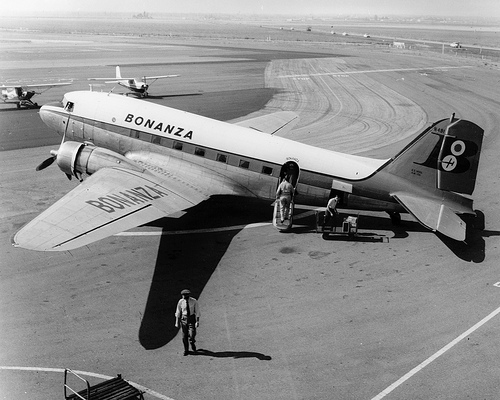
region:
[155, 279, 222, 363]
Person wearing a tie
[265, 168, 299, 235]
Person climbing up the stairs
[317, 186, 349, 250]
Person grabbing a package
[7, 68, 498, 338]
Large plane on the runway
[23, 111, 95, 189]
Large metal airplane propeller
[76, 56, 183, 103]
Small propeller based airplane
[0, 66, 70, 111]
Small propeller based airplane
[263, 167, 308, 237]
Person climbing into an airplane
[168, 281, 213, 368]
Person walking away from an airplane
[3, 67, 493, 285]
Large airplane parked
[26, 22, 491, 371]
A black and white picture.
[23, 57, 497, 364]
Picture of an older airplane.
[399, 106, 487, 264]
The tail of an airplane.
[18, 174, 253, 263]
Left wing of an airplane.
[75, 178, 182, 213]
The word BONANZA on the left wing of airplane.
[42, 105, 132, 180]
Left side engine on an airplane.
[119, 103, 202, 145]
The word BONANZA on the fuselage of an airplane.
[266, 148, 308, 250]
Man is going in the door of the airplane.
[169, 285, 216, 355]
A man is walking away from the airplane.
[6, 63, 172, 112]
Two smaller airplanes.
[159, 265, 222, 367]
man walking in front of plane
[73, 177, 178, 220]
bonanza written on plane wing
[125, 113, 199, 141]
"Bonanza" is the name of the airplane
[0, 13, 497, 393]
Black and white image of airplane field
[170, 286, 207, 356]
Pilot standing next to airplane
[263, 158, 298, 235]
Person walking inside the plane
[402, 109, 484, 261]
Tail end of an airplane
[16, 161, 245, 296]
Left wing of an airplane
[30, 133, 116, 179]
Engine of an airlpane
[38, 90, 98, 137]
The cockpit of an airplane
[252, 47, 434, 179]
Runway where airplanes take off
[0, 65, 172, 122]
Two idle airplanes